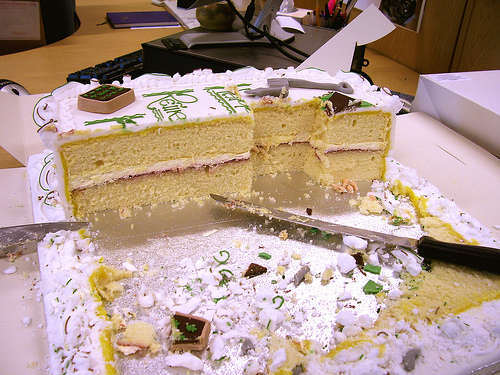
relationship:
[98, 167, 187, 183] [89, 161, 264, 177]
jelly in middle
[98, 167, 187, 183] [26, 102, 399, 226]
jelly in cake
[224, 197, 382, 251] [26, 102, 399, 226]
blade by cake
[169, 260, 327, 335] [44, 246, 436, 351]
crumbs on platter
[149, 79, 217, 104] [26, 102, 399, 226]
designs on cake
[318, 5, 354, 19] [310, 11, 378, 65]
pencils in holder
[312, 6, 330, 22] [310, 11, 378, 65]
pens in holder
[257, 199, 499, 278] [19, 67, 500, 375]
knife on platter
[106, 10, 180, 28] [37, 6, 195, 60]
book on desk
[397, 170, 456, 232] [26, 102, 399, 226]
edge of cake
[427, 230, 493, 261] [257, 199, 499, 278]
handle on knife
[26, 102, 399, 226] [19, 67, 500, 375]
cake on platter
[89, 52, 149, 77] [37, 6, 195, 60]
keyboard on desk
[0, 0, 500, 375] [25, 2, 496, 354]
desk in photo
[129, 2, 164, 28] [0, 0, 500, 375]
book on desk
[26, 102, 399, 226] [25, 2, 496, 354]
cake in photo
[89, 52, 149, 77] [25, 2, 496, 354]
keyboard in photo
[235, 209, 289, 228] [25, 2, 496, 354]
cutting edge in photo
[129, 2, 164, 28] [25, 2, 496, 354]
book in photo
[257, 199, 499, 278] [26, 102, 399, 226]
knife on cake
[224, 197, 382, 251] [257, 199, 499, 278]
blade on knife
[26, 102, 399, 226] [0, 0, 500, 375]
cake on desk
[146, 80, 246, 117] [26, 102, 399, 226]
frosting on cake